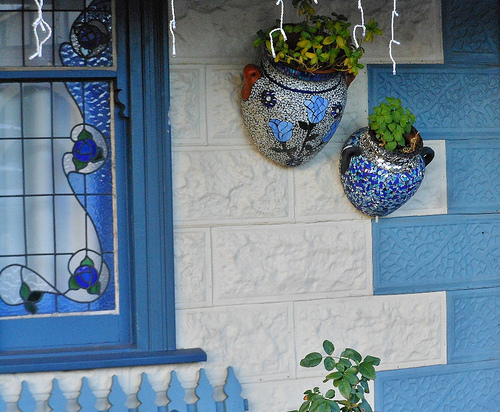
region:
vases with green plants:
[236, 13, 448, 235]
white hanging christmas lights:
[11, 1, 419, 106]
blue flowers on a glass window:
[0, 8, 156, 353]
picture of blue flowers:
[260, 84, 338, 169]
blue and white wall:
[196, 22, 496, 388]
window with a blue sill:
[6, 14, 227, 359]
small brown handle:
[223, 59, 280, 122]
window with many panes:
[0, 76, 125, 348]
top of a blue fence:
[4, 349, 276, 406]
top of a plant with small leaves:
[276, 331, 388, 407]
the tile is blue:
[415, 322, 460, 383]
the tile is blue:
[367, 207, 495, 369]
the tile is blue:
[415, 201, 477, 289]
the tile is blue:
[410, 192, 467, 246]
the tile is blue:
[406, 261, 487, 303]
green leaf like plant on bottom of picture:
[287, 328, 393, 410]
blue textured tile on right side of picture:
[390, 352, 497, 407]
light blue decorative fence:
[157, 354, 262, 409]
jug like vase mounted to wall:
[340, 122, 467, 222]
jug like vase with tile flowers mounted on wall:
[231, 3, 366, 178]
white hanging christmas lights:
[25, 4, 68, 77]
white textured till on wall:
[216, 231, 348, 300]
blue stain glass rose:
[68, 124, 128, 175]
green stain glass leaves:
[17, 276, 57, 324]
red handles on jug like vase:
[235, 60, 289, 112]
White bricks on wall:
[180, 166, 346, 303]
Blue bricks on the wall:
[370, 229, 495, 368]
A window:
[3, 88, 133, 330]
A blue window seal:
[1, 348, 206, 365]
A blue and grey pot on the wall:
[334, 126, 455, 221]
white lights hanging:
[157, 3, 198, 60]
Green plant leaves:
[296, 343, 373, 405]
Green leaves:
[371, 111, 416, 150]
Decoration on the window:
[63, 75, 128, 322]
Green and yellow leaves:
[296, 24, 349, 59]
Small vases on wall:
[232, 50, 432, 215]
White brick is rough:
[213, 221, 373, 293]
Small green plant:
[298, 335, 376, 410]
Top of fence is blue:
[15, 360, 265, 409]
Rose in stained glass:
[66, 118, 122, 198]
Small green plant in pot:
[370, 92, 416, 145]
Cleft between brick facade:
[208, 226, 217, 308]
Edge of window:
[116, 88, 214, 359]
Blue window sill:
[0, 350, 237, 364]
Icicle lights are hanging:
[17, 5, 63, 65]